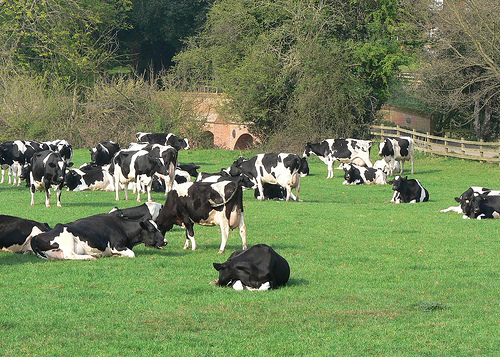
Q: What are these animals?
A: Cows.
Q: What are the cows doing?
A: Grazing.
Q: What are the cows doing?
A: Laying down.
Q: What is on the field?
A: Cows.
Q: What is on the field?
A: Cows.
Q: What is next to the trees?
A: A bridge.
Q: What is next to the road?
A: A fence.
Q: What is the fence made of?
A: Wood.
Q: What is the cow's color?
A: Black and white.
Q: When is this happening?
A: During the day time.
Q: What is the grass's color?
A: Green.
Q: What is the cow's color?
A: Black and white.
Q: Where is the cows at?
A: A field.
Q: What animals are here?
A: Cows.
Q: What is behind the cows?
A: A bridge.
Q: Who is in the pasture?
A: Cows.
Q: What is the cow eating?
A: Grass.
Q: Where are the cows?
A: In a pasture.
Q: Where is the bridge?
A: By the river.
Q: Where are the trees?
A: Behind the cows.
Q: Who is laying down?
A: Cows.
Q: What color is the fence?
A: Brown.